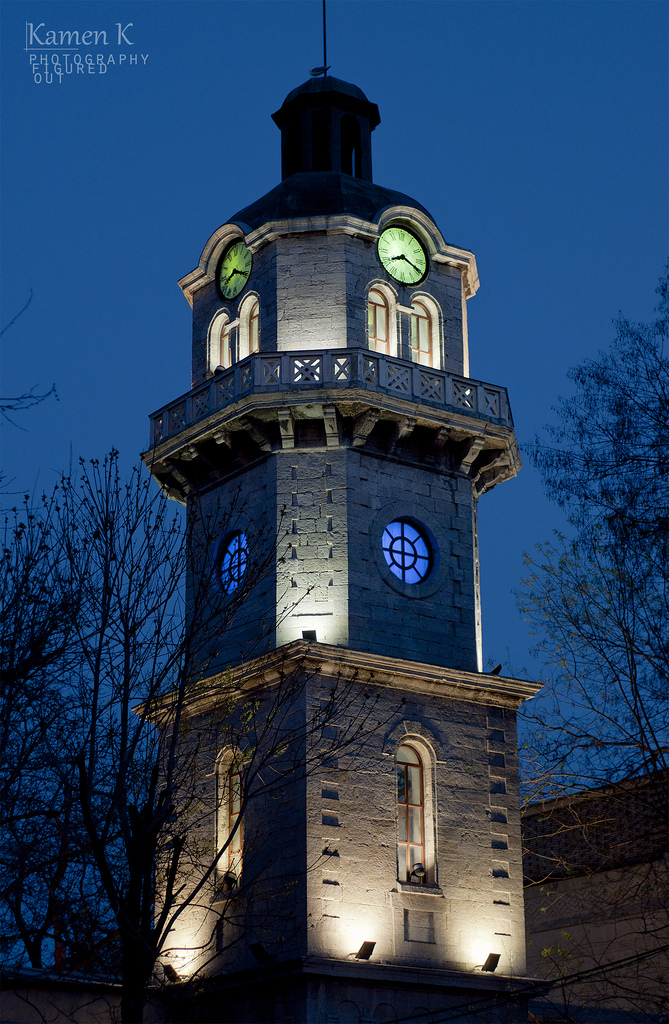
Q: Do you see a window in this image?
A: Yes, there is a window.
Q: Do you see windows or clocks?
A: Yes, there is a window.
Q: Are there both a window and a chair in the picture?
A: No, there is a window but no chairs.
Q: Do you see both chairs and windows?
A: No, there is a window but no chairs.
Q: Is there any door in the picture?
A: No, there are no doors.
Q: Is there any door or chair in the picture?
A: No, there are no doors or chairs.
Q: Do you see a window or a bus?
A: Yes, there is a window.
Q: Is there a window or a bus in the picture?
A: Yes, there is a window.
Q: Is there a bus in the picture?
A: No, there are no buses.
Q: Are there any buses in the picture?
A: No, there are no buses.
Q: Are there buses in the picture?
A: No, there are no buses.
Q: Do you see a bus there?
A: No, there are no buses.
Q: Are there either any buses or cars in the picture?
A: No, there are no buses or cars.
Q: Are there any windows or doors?
A: Yes, there is a window.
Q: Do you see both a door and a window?
A: No, there is a window but no doors.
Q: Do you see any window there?
A: Yes, there is a window.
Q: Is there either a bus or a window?
A: Yes, there is a window.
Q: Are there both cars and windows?
A: No, there is a window but no cars.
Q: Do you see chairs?
A: No, there are no chairs.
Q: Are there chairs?
A: No, there are no chairs.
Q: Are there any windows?
A: Yes, there is a window.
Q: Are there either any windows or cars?
A: Yes, there is a window.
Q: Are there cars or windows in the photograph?
A: Yes, there is a window.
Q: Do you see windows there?
A: Yes, there is a window.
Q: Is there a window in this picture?
A: Yes, there is a window.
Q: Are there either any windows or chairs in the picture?
A: Yes, there is a window.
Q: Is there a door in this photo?
A: No, there are no doors.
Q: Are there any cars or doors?
A: No, there are no doors or cars.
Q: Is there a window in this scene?
A: Yes, there is a window.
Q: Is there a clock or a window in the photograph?
A: Yes, there is a window.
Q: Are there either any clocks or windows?
A: Yes, there is a window.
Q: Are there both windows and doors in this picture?
A: No, there is a window but no doors.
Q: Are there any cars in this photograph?
A: No, there are no cars.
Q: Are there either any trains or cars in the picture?
A: No, there are no cars or trains.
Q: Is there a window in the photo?
A: Yes, there is a window.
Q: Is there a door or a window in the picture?
A: Yes, there is a window.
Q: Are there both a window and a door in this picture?
A: No, there is a window but no doors.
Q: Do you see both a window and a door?
A: No, there is a window but no doors.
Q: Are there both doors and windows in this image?
A: No, there is a window but no doors.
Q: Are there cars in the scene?
A: No, there are no cars.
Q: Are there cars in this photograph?
A: No, there are no cars.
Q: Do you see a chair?
A: No, there are no chairs.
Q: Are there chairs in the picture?
A: No, there are no chairs.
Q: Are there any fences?
A: No, there are no fences.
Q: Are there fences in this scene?
A: No, there are no fences.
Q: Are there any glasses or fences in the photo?
A: No, there are no fences or glasses.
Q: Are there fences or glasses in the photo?
A: No, there are no fences or glasses.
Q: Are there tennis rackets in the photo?
A: No, there are no tennis rackets.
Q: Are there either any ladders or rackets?
A: No, there are no rackets or ladders.